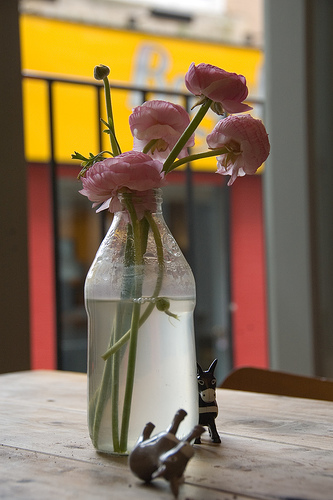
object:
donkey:
[195, 358, 221, 444]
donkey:
[128, 408, 207, 494]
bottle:
[84, 189, 199, 456]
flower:
[78, 150, 164, 201]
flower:
[182, 63, 251, 115]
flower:
[129, 96, 194, 158]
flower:
[207, 113, 270, 186]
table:
[0, 367, 331, 498]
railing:
[20, 74, 267, 380]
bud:
[91, 63, 112, 81]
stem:
[92, 60, 125, 158]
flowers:
[78, 64, 270, 207]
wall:
[24, 17, 265, 164]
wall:
[25, 172, 269, 372]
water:
[85, 298, 199, 450]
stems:
[87, 215, 173, 452]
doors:
[52, 167, 232, 378]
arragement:
[74, 61, 273, 456]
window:
[56, 177, 234, 371]